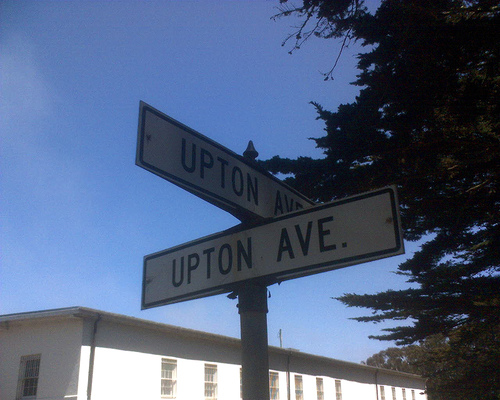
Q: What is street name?
A: Upton ave.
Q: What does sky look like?
A: Blue and clear.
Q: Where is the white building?
A: In background.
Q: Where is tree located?
A: Right of sign.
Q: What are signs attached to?
A: Metal pole.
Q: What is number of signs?
A: Two.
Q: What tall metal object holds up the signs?
A: Pole.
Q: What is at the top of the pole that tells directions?
A: Signs.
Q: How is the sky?
A: Clear.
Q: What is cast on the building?
A: Shadows.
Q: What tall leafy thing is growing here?
A: Tree.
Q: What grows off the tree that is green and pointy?
A: Leaves.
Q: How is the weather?
A: Clear.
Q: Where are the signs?
A: On the pole.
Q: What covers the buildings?
A: Roof.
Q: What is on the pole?
A: Signs.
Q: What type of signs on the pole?
A: Street signs.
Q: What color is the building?
A: White.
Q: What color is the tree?
A: Green.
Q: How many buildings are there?
A: One.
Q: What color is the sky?
A: Blue.